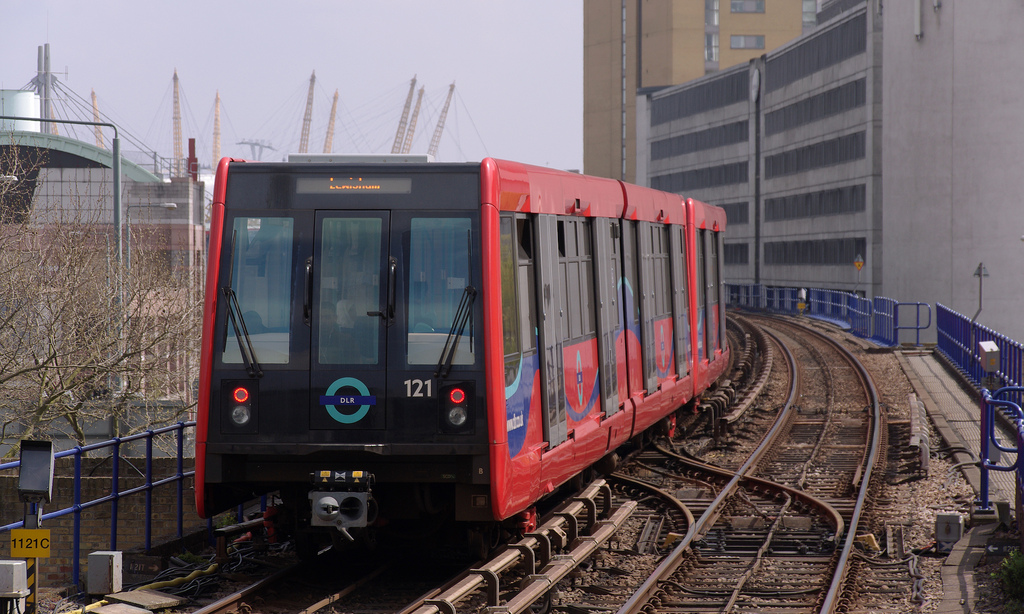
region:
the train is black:
[264, 372, 306, 421]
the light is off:
[438, 407, 474, 430]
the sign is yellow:
[5, 522, 57, 562]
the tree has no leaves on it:
[9, 215, 120, 332]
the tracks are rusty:
[721, 455, 795, 513]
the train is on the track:
[451, 508, 522, 579]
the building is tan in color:
[647, 15, 686, 66]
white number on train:
[401, 366, 436, 402]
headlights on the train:
[217, 377, 262, 434]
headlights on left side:
[438, 384, 476, 441]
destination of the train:
[293, 164, 415, 204]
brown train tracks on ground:
[645, 331, 890, 610]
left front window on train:
[411, 213, 475, 372]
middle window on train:
[306, 210, 389, 375]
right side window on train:
[226, 195, 315, 379]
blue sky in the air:
[471, 6, 588, 152]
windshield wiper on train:
[221, 292, 275, 384]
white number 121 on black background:
[393, 375, 441, 401]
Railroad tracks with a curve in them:
[136, 304, 882, 606]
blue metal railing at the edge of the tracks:
[722, 278, 1021, 501]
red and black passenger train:
[179, 145, 729, 544]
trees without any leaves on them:
[0, 146, 193, 457]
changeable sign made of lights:
[277, 164, 426, 200]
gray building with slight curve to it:
[629, 0, 1022, 345]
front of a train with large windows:
[191, 152, 531, 558]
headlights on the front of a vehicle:
[185, 366, 500, 440]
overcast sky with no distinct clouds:
[4, 3, 593, 180]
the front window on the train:
[230, 215, 486, 367]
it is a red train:
[176, 126, 759, 516]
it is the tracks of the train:
[720, 329, 866, 606]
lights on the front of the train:
[436, 380, 478, 445]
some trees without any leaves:
[8, 221, 201, 428]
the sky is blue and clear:
[21, 18, 576, 162]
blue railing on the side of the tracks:
[811, 290, 1021, 405]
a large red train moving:
[123, 117, 768, 513]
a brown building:
[581, 0, 835, 201]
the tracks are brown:
[667, 319, 873, 611]